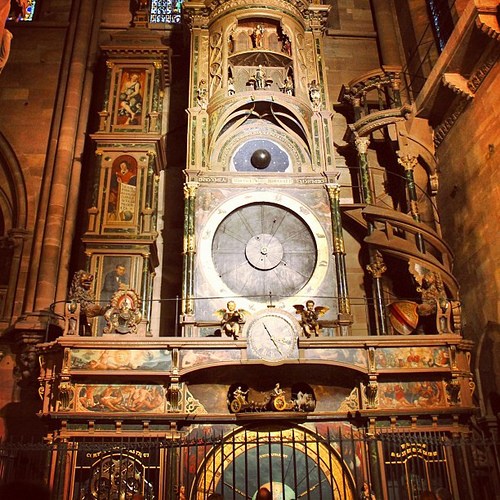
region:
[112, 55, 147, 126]
painting of a woman in a green dress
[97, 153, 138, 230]
painting of a man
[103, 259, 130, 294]
painting of a man in a suit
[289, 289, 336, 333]
angel sitting by a clock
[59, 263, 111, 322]
lion at the bottom of the pictures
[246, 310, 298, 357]
clock in the tower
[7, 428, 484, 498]
metal gate protecting the tower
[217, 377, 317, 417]
people riding in chariots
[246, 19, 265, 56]
tiny statue at the top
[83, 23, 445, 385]
beautiful tower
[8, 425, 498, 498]
black gate in front of clock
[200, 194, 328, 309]
black clock on structure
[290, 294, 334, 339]
angel statue on clock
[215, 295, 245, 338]
statue of an angel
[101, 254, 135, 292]
painting on the wall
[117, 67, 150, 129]
painting of woman on wall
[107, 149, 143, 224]
older painting of man on wall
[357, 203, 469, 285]
stairway in the sanctuary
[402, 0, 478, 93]
balcony on top of sanctuary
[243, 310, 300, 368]
small clock in church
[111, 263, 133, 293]
the man is on the window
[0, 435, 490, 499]
the fence is made of metal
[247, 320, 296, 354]
the clock is on the wall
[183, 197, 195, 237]
the pillar is green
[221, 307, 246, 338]
the statue is on the building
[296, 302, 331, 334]
the statue is on the building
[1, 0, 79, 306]
the building is brown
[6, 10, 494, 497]
the scene is indoor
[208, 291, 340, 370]
cherub angels and a clock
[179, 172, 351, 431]
a clock, two anges and a glockenspiel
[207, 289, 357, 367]
two cherub angels on a mantel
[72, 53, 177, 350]
antique paintings of dignitaries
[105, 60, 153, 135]
a very old portrait of a woman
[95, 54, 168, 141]
a very old painting of a woman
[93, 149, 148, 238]
a historic portrait of a man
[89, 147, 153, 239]
historic painting of a man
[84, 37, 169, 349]
three portraits in a triptych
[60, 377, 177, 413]
ancient painting set in wood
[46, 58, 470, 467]
The front of a cathedral.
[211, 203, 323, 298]
A circular glass piece above the clock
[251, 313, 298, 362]
A clock under the glass piece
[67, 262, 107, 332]
A lion to the left of the clock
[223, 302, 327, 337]
Two angles immediately flanking the clock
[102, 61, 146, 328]
Three paintings on the left side of the clock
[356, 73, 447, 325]
A spiral staircase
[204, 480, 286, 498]
The heads of two tourist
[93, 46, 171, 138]
picture of woman on the shelf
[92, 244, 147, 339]
picture of man on the shelf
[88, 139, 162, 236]
picture of man on the shelf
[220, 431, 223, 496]
fence has a post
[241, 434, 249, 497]
fence has a post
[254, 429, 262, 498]
fence has a post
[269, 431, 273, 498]
fence has a post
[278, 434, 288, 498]
fence has a post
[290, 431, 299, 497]
fence has a post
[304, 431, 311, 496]
fence has a post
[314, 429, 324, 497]
fence has a post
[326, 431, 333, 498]
fence has a post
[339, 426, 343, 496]
fence has a post